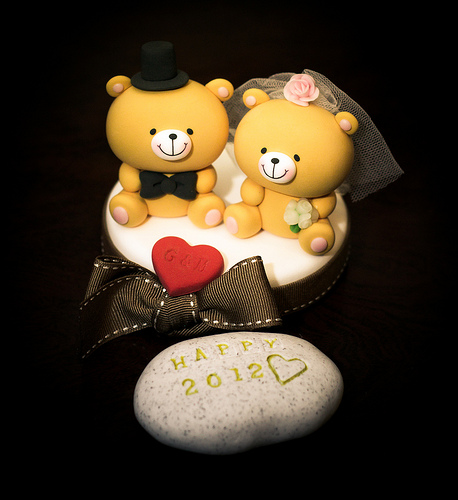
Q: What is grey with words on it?
A: Stone.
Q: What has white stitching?
A: Black ribbon.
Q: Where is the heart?
A: On stone.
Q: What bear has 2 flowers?
A: On right.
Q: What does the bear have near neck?
A: Bowtie.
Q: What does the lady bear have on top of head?
A: Veil with rose.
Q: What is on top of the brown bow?
A: Heart.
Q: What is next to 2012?
A: Heart.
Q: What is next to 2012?
A: Heart.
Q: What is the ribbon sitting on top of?
A: Cake.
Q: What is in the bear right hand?
A: Carnation.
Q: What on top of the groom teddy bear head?
A: Hat.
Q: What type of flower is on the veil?
A: Rose.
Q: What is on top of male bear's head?
A: Hat.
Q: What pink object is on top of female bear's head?
A: Flower.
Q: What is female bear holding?
A: Bouquet.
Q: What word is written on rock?
A: Happy.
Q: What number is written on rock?
A: 2012.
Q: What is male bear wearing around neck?
A: Bow tie.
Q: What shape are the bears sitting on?
A: Circle.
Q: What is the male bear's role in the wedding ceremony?
A: Groom.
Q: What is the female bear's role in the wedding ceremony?
A: Bride.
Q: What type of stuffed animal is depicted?
A: Teddy bear.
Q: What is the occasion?
A: Wedding.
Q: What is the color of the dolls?
A: Brown.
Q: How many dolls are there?
A: 2.